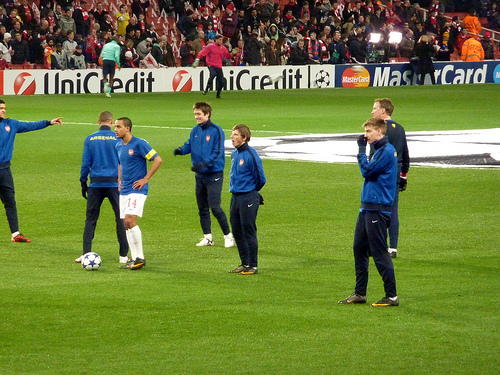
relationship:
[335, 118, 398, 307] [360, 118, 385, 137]
blueshirt person has brown hair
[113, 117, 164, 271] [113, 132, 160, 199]
blueshirt person wearing shirt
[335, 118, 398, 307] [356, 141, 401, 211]
blueshirt person wearing blue jacket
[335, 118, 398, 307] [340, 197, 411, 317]
blueshirt person wearing pants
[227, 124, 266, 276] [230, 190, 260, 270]
blueshirt person wearing pants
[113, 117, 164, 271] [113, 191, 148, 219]
blueshirt person in shorts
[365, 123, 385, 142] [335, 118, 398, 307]
head of blueshirt person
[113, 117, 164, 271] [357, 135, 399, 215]
blueshirt person wearing blue jacket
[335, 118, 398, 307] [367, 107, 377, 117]
blueshirt person wiping nose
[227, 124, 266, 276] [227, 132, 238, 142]
blueshirt person wiping nose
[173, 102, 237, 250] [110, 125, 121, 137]
blueshirt person wiping nose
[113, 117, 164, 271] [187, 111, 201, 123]
blueshirt person wiping nose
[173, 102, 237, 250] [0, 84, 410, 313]
blueshirt person at teammate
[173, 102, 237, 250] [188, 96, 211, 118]
blueshirt person with hair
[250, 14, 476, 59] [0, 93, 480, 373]
crowd watching soccer game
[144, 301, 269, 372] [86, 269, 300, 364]
part of a field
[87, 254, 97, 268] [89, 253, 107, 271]
part of a ball part